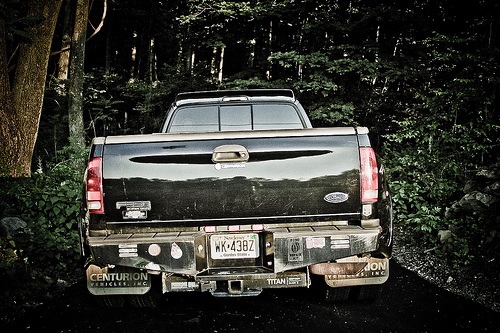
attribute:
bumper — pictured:
[75, 227, 397, 296]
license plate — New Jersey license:
[204, 228, 269, 264]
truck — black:
[108, 87, 380, 276]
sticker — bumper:
[87, 262, 157, 297]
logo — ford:
[323, 190, 349, 205]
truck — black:
[83, 87, 394, 293]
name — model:
[117, 200, 149, 210]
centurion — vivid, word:
[87, 270, 148, 287]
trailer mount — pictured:
[227, 274, 247, 296]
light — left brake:
[85, 160, 107, 210]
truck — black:
[73, 79, 398, 301]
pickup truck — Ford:
[70, 80, 401, 302]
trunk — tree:
[0, 0, 58, 180]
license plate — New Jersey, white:
[208, 232, 259, 259]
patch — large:
[301, 311, 329, 322]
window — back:
[163, 102, 306, 132]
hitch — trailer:
[228, 277, 243, 294]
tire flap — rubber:
[82, 264, 154, 295]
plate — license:
[208, 233, 259, 261]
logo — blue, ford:
[322, 190, 350, 200]